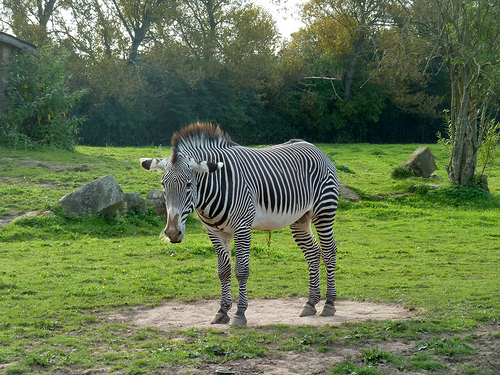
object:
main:
[170, 124, 244, 161]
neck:
[176, 139, 221, 219]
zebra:
[140, 120, 340, 328]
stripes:
[264, 148, 273, 208]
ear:
[139, 157, 164, 170]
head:
[142, 155, 224, 243]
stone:
[57, 175, 129, 223]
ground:
[0, 141, 497, 374]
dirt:
[139, 292, 418, 336]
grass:
[38, 236, 151, 301]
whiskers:
[158, 231, 170, 242]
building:
[0, 27, 43, 152]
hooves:
[229, 313, 247, 326]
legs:
[233, 231, 252, 316]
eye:
[186, 181, 193, 189]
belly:
[253, 212, 313, 233]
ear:
[189, 159, 224, 173]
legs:
[315, 197, 338, 307]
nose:
[176, 229, 183, 237]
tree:
[179, 3, 239, 123]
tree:
[100, 2, 183, 118]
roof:
[1, 29, 39, 57]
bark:
[457, 122, 474, 162]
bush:
[11, 56, 74, 152]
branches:
[218, 18, 245, 39]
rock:
[399, 146, 436, 178]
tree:
[441, 7, 497, 188]